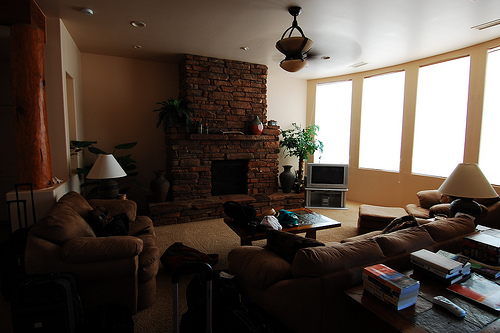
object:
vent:
[472, 17, 499, 32]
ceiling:
[4, 0, 495, 77]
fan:
[275, 5, 315, 72]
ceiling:
[49, 0, 500, 79]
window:
[358, 70, 405, 173]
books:
[360, 263, 419, 310]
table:
[295, 224, 493, 306]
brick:
[147, 54, 303, 224]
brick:
[190, 151, 200, 156]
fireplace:
[204, 155, 253, 198]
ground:
[434, 159, 446, 181]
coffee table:
[224, 208, 341, 247]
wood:
[304, 209, 339, 229]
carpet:
[173, 220, 222, 246]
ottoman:
[355, 202, 408, 232]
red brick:
[255, 157, 275, 180]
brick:
[225, 67, 241, 75]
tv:
[303, 162, 348, 184]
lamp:
[435, 161, 499, 231]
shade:
[437, 163, 500, 228]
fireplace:
[157, 52, 299, 218]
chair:
[403, 186, 470, 223]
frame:
[300, 39, 500, 212]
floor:
[139, 199, 356, 329]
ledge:
[166, 130, 282, 141]